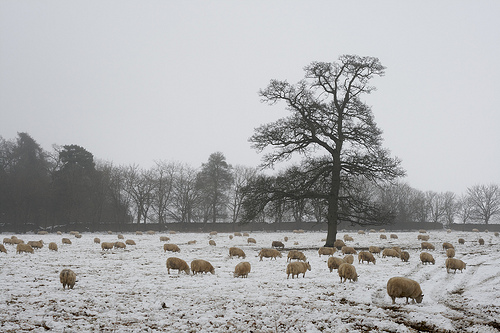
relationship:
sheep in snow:
[234, 261, 251, 280] [0, 231, 500, 332]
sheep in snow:
[166, 257, 190, 276] [0, 231, 500, 332]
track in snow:
[371, 261, 446, 305] [0, 231, 500, 332]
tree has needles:
[52, 142, 110, 225] [70, 185, 77, 191]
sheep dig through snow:
[234, 261, 251, 280] [0, 231, 500, 332]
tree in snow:
[248, 54, 407, 247] [0, 231, 500, 332]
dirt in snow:
[410, 321, 428, 330] [0, 231, 500, 332]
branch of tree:
[312, 53, 353, 105] [248, 54, 407, 247]